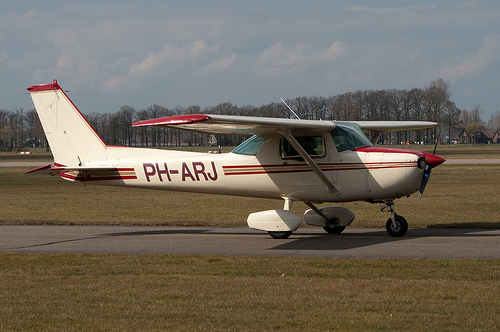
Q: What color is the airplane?
A: White.